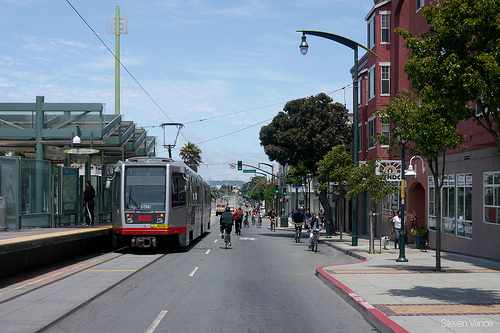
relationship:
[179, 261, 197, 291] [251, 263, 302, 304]
lines on road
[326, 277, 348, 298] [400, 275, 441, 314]
curb on sidewalk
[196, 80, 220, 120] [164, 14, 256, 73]
clouds are in sky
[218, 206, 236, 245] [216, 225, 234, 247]
man riding bicycle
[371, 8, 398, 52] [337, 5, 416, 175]
window on building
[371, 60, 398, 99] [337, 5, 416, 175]
window on building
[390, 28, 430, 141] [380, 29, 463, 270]
leaves are on tree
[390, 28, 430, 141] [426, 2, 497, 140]
leaves are on tree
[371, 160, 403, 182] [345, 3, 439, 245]
sign on building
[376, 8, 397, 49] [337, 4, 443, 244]
window on building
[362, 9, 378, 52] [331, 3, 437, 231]
window on building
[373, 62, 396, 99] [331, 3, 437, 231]
window on building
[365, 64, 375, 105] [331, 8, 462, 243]
window on building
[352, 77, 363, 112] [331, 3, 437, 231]
window on building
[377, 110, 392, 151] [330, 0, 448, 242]
window on building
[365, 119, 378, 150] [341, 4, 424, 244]
window on building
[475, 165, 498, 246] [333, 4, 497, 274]
window on building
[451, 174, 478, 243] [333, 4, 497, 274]
window on building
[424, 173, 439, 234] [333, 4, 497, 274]
window on building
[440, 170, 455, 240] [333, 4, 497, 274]
window on building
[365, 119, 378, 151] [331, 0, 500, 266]
window on building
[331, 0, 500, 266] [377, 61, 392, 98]
building on window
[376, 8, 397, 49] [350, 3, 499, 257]
window on building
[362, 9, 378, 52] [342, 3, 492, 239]
window on building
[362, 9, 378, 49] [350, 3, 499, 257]
window on building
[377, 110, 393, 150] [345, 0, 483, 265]
window on building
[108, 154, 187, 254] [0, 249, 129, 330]
train has tracks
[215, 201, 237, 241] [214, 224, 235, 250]
man on bicycle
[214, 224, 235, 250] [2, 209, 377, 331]
bicycle in street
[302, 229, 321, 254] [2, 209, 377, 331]
bicycle in street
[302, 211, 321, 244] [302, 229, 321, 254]
man on bicycle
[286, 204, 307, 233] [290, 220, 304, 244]
man on bicycle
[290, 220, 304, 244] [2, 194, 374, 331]
bicycle in street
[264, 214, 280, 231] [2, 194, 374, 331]
bicycle in street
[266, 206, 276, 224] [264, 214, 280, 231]
man on bicycle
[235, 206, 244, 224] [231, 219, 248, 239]
man on bicycle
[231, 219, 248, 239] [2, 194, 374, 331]
bicycle in street